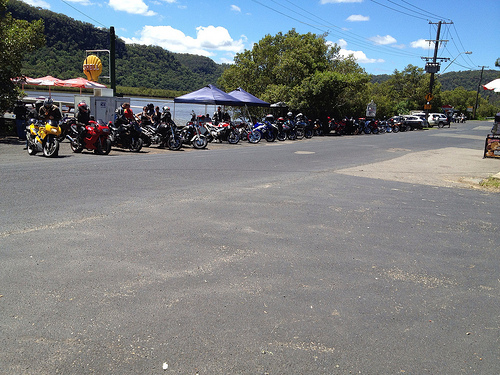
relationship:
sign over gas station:
[79, 54, 103, 78] [23, 82, 107, 102]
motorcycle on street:
[26, 121, 63, 155] [64, 148, 407, 354]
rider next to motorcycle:
[39, 97, 62, 120] [26, 121, 63, 155]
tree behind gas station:
[2, 13, 37, 56] [23, 82, 107, 102]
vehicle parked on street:
[401, 114, 427, 128] [64, 148, 407, 354]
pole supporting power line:
[108, 29, 121, 90] [65, 2, 89, 14]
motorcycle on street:
[72, 129, 112, 153] [64, 148, 407, 354]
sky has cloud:
[86, 2, 491, 53] [199, 24, 225, 47]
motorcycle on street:
[110, 121, 141, 147] [64, 148, 407, 354]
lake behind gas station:
[130, 97, 199, 117] [23, 82, 107, 102]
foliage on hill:
[20, 10, 198, 87] [140, 51, 154, 56]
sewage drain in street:
[292, 146, 317, 157] [64, 148, 407, 354]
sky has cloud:
[86, 2, 491, 53] [142, 27, 178, 41]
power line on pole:
[377, 2, 394, 12] [434, 22, 443, 65]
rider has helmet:
[71, 105, 93, 126] [78, 104, 88, 108]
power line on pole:
[326, 27, 344, 37] [434, 22, 443, 65]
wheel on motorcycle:
[42, 140, 57, 153] [26, 121, 63, 155]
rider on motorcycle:
[113, 105, 130, 124] [110, 121, 141, 147]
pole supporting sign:
[87, 48, 111, 54] [79, 54, 103, 78]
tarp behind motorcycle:
[170, 90, 244, 108] [238, 125, 251, 139]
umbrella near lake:
[30, 77, 55, 85] [130, 97, 199, 117]